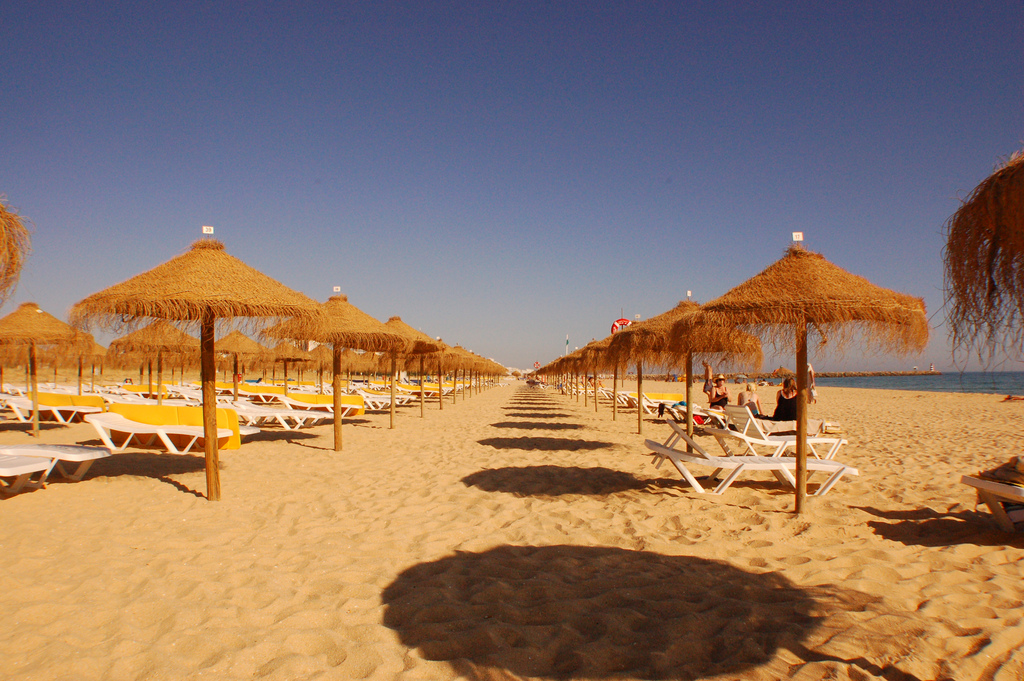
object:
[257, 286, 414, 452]
umbrella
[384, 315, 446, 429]
umbrella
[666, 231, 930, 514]
umbrella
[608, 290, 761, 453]
umbrella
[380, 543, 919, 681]
shadow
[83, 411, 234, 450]
chair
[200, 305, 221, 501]
pole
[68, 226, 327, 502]
umbrella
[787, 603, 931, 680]
lumps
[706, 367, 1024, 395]
water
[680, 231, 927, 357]
umbrella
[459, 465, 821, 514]
shadow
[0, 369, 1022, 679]
beach